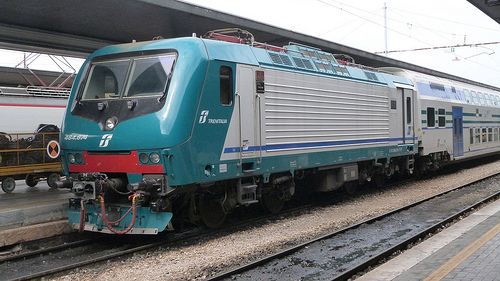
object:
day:
[0, 0, 500, 281]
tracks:
[320, 192, 500, 281]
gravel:
[192, 237, 256, 251]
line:
[421, 219, 498, 281]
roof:
[0, 0, 500, 90]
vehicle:
[0, 123, 64, 193]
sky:
[173, 0, 500, 88]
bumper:
[68, 151, 169, 179]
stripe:
[419, 224, 500, 281]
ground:
[355, 199, 500, 281]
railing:
[49, 30, 500, 240]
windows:
[81, 58, 133, 101]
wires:
[99, 195, 142, 235]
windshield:
[80, 50, 180, 101]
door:
[452, 106, 465, 156]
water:
[321, 243, 356, 265]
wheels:
[195, 192, 235, 229]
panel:
[62, 154, 152, 176]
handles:
[284, 40, 327, 51]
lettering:
[198, 109, 228, 124]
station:
[0, 0, 497, 281]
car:
[403, 69, 499, 164]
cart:
[6, 136, 72, 171]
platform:
[0, 185, 72, 213]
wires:
[303, 0, 500, 74]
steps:
[236, 185, 259, 191]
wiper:
[157, 58, 178, 99]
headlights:
[149, 152, 160, 163]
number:
[65, 133, 87, 141]